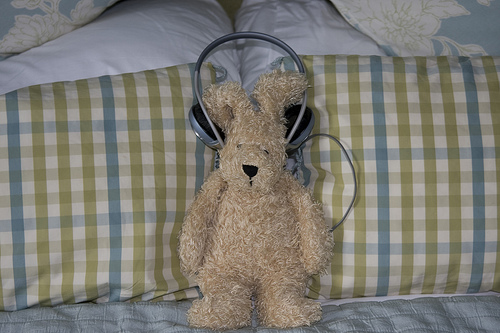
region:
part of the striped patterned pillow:
[445, 208, 494, 287]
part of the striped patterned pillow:
[383, 225, 430, 285]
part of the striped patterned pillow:
[343, 240, 375, 287]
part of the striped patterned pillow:
[122, 218, 158, 288]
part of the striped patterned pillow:
[61, 233, 119, 290]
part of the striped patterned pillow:
[6, 184, 55, 229]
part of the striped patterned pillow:
[81, 180, 134, 213]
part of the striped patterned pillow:
[69, 98, 128, 148]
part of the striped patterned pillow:
[389, 78, 448, 129]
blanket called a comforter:
[2, 311, 185, 331]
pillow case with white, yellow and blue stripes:
[2, 92, 139, 301]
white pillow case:
[93, 18, 141, 63]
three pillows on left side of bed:
[359, 2, 464, 262]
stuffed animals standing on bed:
[178, 73, 333, 330]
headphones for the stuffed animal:
[187, 30, 317, 150]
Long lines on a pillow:
[6, 93, 26, 318]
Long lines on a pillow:
[26, 78, 51, 313]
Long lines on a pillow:
[45, 68, 79, 304]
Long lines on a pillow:
[67, 73, 107, 303]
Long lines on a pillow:
[121, 66, 146, 308]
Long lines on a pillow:
[144, 63, 175, 301]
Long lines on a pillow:
[340, 51, 386, 291]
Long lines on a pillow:
[374, 41, 424, 297]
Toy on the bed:
[170, 64, 361, 329]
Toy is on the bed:
[167, 65, 351, 330]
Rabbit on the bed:
[165, 62, 351, 331]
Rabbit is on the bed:
[163, 63, 354, 329]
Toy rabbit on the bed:
[170, 66, 347, 329]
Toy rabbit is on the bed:
[173, 65, 343, 331]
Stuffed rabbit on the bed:
[164, 65, 349, 332]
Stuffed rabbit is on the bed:
[172, 63, 341, 330]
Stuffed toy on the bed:
[165, 60, 346, 330]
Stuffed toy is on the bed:
[172, 57, 337, 329]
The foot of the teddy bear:
[186, 281, 250, 329]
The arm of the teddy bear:
[171, 175, 216, 269]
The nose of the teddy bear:
[237, 157, 262, 181]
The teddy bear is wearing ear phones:
[186, 28, 316, 153]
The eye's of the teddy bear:
[228, 138, 275, 160]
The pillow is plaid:
[346, 70, 498, 294]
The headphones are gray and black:
[191, 20, 328, 152]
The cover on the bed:
[26, 295, 492, 330]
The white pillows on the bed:
[11, 3, 459, 92]